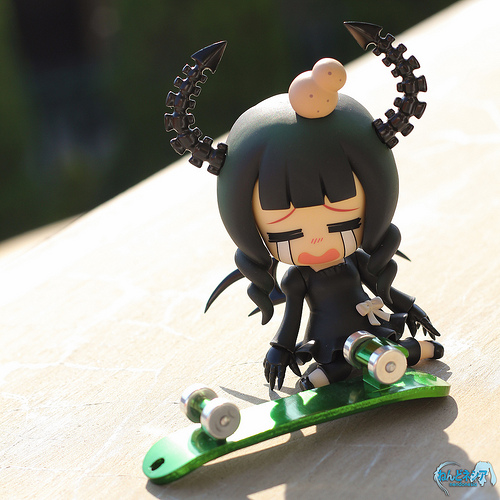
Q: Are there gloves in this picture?
A: Yes, there are gloves.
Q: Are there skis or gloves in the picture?
A: Yes, there are gloves.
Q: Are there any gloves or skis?
A: Yes, there are gloves.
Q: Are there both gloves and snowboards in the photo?
A: No, there are gloves but no snowboards.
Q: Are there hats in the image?
A: No, there are no hats.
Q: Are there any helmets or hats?
A: No, there are no hats or helmets.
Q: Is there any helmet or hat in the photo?
A: No, there are no hats or helmets.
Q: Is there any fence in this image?
A: No, there are no fences.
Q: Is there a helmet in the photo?
A: No, there are no helmets.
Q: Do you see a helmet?
A: No, there are no helmets.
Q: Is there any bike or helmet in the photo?
A: No, there are no helmets or bikes.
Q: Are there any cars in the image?
A: No, there are no cars.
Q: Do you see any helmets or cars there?
A: No, there are no cars or helmets.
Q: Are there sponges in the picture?
A: No, there are no sponges.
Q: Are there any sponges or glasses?
A: No, there are no sponges or glasses.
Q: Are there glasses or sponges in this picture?
A: No, there are no sponges or glasses.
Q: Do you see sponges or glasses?
A: No, there are no sponges or glasses.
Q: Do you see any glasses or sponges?
A: No, there are no sponges or glasses.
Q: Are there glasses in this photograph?
A: No, there are no glasses.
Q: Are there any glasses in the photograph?
A: No, there are no glasses.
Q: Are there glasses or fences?
A: No, there are no glasses or fences.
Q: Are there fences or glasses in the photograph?
A: No, there are no glasses or fences.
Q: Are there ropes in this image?
A: No, there are no ropes.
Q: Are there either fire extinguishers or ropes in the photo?
A: No, there are no ropes or fire extinguishers.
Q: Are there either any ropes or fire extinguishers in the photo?
A: No, there are no ropes or fire extinguishers.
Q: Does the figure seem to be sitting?
A: Yes, the figure is sitting.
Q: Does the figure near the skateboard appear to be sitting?
A: Yes, the figure is sitting.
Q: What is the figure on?
A: The figure is on the table.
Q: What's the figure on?
A: The figure is on the table.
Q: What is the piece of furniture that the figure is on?
A: The piece of furniture is a table.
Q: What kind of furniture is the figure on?
A: The figure is on the table.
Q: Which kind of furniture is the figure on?
A: The figure is on the table.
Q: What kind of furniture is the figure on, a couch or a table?
A: The figure is on a table.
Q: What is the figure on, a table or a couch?
A: The figure is on a table.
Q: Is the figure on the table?
A: Yes, the figure is on the table.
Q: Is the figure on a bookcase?
A: No, the figure is on the table.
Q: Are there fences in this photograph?
A: No, there are no fences.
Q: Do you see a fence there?
A: No, there are no fences.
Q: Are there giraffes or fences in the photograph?
A: No, there are no fences or giraffes.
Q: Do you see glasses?
A: No, there are no glasses.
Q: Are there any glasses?
A: No, there are no glasses.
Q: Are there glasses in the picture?
A: No, there are no glasses.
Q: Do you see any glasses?
A: No, there are no glasses.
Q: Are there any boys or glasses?
A: No, there are no glasses or boys.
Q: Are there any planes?
A: No, there are no planes.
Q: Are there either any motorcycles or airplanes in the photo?
A: No, there are no airplanes or motorcycles.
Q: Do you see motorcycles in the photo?
A: No, there are no motorcycles.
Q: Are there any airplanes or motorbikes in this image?
A: No, there are no motorbikes or airplanes.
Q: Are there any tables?
A: Yes, there is a table.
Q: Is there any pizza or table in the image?
A: Yes, there is a table.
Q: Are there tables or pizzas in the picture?
A: Yes, there is a table.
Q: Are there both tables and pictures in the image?
A: No, there is a table but no pictures.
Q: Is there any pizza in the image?
A: No, there are no pizzas.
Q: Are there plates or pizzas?
A: No, there are no pizzas or plates.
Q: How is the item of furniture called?
A: The piece of furniture is a table.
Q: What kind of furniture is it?
A: The piece of furniture is a table.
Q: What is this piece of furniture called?
A: This is a table.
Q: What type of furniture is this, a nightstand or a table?
A: This is a table.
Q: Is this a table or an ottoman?
A: This is a table.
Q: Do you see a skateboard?
A: Yes, there is a skateboard.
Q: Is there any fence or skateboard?
A: Yes, there is a skateboard.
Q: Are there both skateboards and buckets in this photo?
A: No, there is a skateboard but no buckets.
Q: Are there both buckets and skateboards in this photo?
A: No, there is a skateboard but no buckets.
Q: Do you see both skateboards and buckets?
A: No, there is a skateboard but no buckets.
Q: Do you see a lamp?
A: No, there are no lamps.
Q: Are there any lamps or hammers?
A: No, there are no lamps or hammers.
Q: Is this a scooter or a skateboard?
A: This is a skateboard.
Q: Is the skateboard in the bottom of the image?
A: Yes, the skateboard is in the bottom of the image.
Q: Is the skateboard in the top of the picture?
A: No, the skateboard is in the bottom of the image.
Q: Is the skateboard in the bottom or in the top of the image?
A: The skateboard is in the bottom of the image.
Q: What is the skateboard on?
A: The skateboard is on the table.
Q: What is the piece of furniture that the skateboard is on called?
A: The piece of furniture is a table.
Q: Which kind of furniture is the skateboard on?
A: The skateboard is on the table.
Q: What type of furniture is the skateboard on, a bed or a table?
A: The skateboard is on a table.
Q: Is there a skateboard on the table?
A: Yes, there is a skateboard on the table.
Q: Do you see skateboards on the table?
A: Yes, there is a skateboard on the table.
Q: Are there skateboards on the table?
A: Yes, there is a skateboard on the table.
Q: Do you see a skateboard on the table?
A: Yes, there is a skateboard on the table.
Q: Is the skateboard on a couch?
A: No, the skateboard is on the table.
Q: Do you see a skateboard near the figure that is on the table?
A: Yes, there is a skateboard near the figure.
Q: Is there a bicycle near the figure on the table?
A: No, there is a skateboard near the figure.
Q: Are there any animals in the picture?
A: No, there are no animals.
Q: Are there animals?
A: No, there are no animals.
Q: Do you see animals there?
A: No, there are no animals.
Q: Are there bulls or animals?
A: No, there are no animals or bulls.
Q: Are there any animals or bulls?
A: No, there are no animals or bulls.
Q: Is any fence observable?
A: No, there are no fences.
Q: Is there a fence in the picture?
A: No, there are no fences.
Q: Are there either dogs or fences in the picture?
A: No, there are no fences or dogs.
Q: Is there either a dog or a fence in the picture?
A: No, there are no fences or dogs.